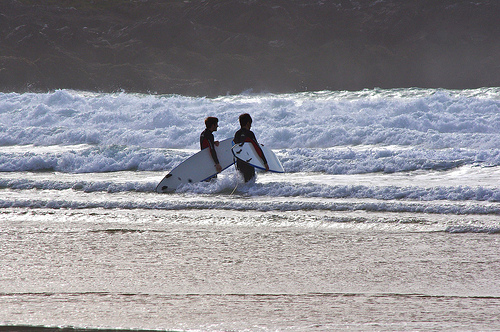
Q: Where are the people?
A: In the water.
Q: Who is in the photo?
A: Surfers.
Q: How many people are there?
A: Two.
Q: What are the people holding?
A: Surfboards.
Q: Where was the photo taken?
A: The beach.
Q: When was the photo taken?
A: During the day.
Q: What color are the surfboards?
A: White.